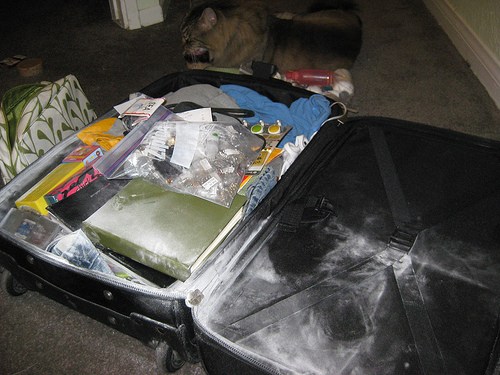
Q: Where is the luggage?
A: Floor.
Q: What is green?
A: Book.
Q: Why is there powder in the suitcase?
A: It exploded.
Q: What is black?
A: Luggage.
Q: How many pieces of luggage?
A: One.